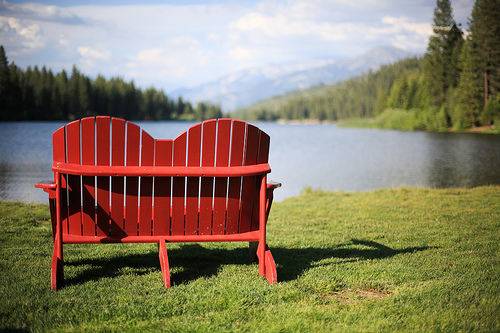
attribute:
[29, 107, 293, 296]
bench — casting, red, plastic, screwed, wooden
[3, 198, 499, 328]
grass — green, dirty, lush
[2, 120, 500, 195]
water — smooth, calm, beautiful, shiny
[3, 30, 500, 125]
trees — green, blurry, tall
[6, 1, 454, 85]
sky — cloudy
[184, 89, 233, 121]
tree — distant